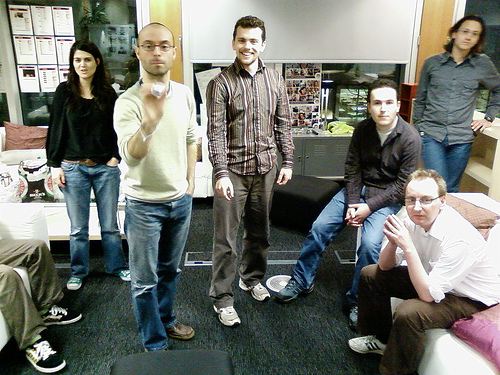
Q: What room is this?
A: It is an office.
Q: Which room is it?
A: It is an office.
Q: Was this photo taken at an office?
A: Yes, it was taken in an office.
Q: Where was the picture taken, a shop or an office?
A: It was taken at an office.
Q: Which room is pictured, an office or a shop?
A: It is an office.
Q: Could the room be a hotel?
A: No, it is an office.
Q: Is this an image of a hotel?
A: No, the picture is showing an office.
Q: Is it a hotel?
A: No, it is an office.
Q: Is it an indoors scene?
A: Yes, it is indoors.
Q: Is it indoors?
A: Yes, it is indoors.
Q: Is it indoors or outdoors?
A: It is indoors.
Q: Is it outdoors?
A: No, it is indoors.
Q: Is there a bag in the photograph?
A: No, there are no bags.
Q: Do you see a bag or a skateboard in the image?
A: No, there are no bags or skateboards.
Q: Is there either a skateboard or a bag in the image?
A: No, there are no bags or skateboards.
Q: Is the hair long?
A: Yes, the hair is long.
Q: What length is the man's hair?
A: The hair is long.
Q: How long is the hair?
A: The hair is long.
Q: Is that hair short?
A: No, the hair is long.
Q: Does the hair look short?
A: No, the hair is long.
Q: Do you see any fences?
A: No, there are no fences.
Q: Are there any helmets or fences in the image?
A: No, there are no fences or helmets.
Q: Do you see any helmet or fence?
A: No, there are no fences or helmets.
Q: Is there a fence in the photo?
A: No, there are no fences.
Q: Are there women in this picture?
A: Yes, there is a woman.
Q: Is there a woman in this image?
A: Yes, there is a woman.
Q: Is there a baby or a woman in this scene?
A: Yes, there is a woman.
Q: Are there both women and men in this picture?
A: Yes, there are both a woman and a man.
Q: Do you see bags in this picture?
A: No, there are no bags.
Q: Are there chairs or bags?
A: No, there are no bags or chairs.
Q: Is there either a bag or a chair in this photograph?
A: No, there are no bags or chairs.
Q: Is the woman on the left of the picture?
A: Yes, the woman is on the left of the image.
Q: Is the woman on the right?
A: No, the woman is on the left of the image.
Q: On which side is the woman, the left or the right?
A: The woman is on the left of the image.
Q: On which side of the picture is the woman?
A: The woman is on the left of the image.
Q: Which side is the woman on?
A: The woman is on the left of the image.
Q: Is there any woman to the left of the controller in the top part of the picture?
A: Yes, there is a woman to the left of the controller.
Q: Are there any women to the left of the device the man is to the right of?
A: Yes, there is a woman to the left of the controller.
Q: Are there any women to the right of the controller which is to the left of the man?
A: No, the woman is to the left of the controller.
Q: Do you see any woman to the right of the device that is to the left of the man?
A: No, the woman is to the left of the controller.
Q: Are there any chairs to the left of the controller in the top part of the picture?
A: No, there is a woman to the left of the controller.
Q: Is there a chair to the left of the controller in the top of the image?
A: No, there is a woman to the left of the controller.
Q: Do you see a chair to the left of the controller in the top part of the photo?
A: No, there is a woman to the left of the controller.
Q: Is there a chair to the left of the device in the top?
A: No, there is a woman to the left of the controller.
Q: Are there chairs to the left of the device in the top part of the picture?
A: No, there is a woman to the left of the controller.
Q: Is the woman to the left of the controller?
A: Yes, the woman is to the left of the controller.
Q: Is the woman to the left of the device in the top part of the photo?
A: Yes, the woman is to the left of the controller.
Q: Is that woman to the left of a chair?
A: No, the woman is to the left of the controller.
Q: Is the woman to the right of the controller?
A: No, the woman is to the left of the controller.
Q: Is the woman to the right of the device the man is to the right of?
A: No, the woman is to the left of the controller.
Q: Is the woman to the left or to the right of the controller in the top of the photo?
A: The woman is to the left of the controller.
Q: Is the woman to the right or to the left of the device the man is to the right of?
A: The woman is to the left of the controller.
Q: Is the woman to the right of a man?
A: No, the woman is to the left of a man.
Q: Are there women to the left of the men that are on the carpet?
A: Yes, there is a woman to the left of the men.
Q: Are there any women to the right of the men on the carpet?
A: No, the woman is to the left of the men.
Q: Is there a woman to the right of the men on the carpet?
A: No, the woman is to the left of the men.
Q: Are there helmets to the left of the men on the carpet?
A: No, there is a woman to the left of the men.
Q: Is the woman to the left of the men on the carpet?
A: Yes, the woman is to the left of the men.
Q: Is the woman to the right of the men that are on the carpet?
A: No, the woman is to the left of the men.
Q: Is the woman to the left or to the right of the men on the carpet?
A: The woman is to the left of the men.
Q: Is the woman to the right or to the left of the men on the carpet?
A: The woman is to the left of the men.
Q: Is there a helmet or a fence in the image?
A: No, there are no helmets or fences.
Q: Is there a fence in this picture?
A: No, there are no fences.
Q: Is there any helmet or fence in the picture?
A: No, there are no fences or helmets.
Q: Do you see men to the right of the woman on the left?
A: Yes, there is a man to the right of the woman.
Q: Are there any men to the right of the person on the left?
A: Yes, there is a man to the right of the woman.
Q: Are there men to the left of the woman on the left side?
A: No, the man is to the right of the woman.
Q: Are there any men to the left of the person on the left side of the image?
A: No, the man is to the right of the woman.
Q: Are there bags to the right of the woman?
A: No, there is a man to the right of the woman.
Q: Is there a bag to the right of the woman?
A: No, there is a man to the right of the woman.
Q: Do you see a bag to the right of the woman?
A: No, there is a man to the right of the woman.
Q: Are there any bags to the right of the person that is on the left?
A: No, there is a man to the right of the woman.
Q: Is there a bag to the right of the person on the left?
A: No, there is a man to the right of the woman.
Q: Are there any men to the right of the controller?
A: Yes, there is a man to the right of the controller.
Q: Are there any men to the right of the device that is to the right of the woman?
A: Yes, there is a man to the right of the controller.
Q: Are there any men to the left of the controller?
A: No, the man is to the right of the controller.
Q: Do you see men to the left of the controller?
A: No, the man is to the right of the controller.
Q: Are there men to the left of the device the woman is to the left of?
A: No, the man is to the right of the controller.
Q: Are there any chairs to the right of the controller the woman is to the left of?
A: No, there is a man to the right of the controller.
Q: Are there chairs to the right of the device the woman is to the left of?
A: No, there is a man to the right of the controller.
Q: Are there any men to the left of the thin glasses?
A: Yes, there is a man to the left of the glasses.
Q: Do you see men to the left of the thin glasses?
A: Yes, there is a man to the left of the glasses.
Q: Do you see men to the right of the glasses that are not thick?
A: No, the man is to the left of the glasses.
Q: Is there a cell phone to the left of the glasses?
A: No, there is a man to the left of the glasses.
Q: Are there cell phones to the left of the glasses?
A: No, there is a man to the left of the glasses.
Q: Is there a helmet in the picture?
A: No, there are no helmets.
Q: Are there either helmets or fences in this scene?
A: No, there are no helmets or fences.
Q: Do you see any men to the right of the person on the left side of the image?
A: Yes, there is a man to the right of the woman.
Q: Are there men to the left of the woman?
A: No, the man is to the right of the woman.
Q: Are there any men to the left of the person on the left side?
A: No, the man is to the right of the woman.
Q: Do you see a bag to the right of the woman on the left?
A: No, there is a man to the right of the woman.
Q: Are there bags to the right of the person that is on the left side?
A: No, there is a man to the right of the woman.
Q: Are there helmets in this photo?
A: No, there are no helmets.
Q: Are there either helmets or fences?
A: No, there are no helmets or fences.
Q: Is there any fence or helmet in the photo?
A: No, there are no helmets or fences.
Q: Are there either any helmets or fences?
A: No, there are no fences or helmets.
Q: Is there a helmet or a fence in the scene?
A: No, there are no fences or helmets.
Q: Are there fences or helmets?
A: No, there are no fences or helmets.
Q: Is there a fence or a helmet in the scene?
A: No, there are no fences or helmets.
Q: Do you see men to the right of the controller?
A: Yes, there is a man to the right of the controller.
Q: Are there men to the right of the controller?
A: Yes, there is a man to the right of the controller.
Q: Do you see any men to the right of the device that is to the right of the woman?
A: Yes, there is a man to the right of the controller.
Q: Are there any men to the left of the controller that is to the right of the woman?
A: No, the man is to the right of the controller.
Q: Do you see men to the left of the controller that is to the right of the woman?
A: No, the man is to the right of the controller.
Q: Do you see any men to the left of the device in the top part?
A: No, the man is to the right of the controller.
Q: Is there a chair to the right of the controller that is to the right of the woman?
A: No, there is a man to the right of the controller.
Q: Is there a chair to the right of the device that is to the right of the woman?
A: No, there is a man to the right of the controller.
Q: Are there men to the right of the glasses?
A: No, the man is to the left of the glasses.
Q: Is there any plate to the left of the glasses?
A: No, there is a man to the left of the glasses.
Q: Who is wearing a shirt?
A: The man is wearing a shirt.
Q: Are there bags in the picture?
A: No, there are no bags.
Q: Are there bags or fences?
A: No, there are no bags or fences.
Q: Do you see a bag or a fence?
A: No, there are no bags or fences.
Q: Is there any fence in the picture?
A: No, there are no fences.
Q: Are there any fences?
A: No, there are no fences.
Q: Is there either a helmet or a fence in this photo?
A: No, there are no fences or helmets.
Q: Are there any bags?
A: No, there are no bags.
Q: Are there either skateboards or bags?
A: No, there are no bags or skateboards.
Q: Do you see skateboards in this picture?
A: No, there are no skateboards.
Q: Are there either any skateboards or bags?
A: No, there are no skateboards or bags.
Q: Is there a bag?
A: No, there are no bags.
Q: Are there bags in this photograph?
A: No, there are no bags.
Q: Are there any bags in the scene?
A: No, there are no bags.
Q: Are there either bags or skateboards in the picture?
A: No, there are no bags or skateboards.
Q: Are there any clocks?
A: No, there are no clocks.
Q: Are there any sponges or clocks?
A: No, there are no clocks or sponges.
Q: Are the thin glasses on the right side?
A: Yes, the glasses are on the right of the image.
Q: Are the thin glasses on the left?
A: No, the glasses are on the right of the image.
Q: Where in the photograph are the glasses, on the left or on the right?
A: The glasses are on the right of the image.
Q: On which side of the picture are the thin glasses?
A: The glasses are on the right of the image.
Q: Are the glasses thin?
A: Yes, the glasses are thin.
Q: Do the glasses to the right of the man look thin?
A: Yes, the glasses are thin.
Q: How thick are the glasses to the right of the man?
A: The glasses are thin.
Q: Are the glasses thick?
A: No, the glasses are thin.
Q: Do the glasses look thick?
A: No, the glasses are thin.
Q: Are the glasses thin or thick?
A: The glasses are thin.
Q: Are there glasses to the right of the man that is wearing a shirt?
A: Yes, there are glasses to the right of the man.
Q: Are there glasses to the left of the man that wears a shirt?
A: No, the glasses are to the right of the man.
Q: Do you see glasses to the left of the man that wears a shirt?
A: No, the glasses are to the right of the man.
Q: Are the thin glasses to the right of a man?
A: Yes, the glasses are to the right of a man.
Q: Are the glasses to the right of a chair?
A: No, the glasses are to the right of a man.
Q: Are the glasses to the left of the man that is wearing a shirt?
A: No, the glasses are to the right of the man.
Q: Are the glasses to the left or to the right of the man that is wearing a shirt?
A: The glasses are to the right of the man.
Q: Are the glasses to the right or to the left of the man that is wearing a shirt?
A: The glasses are to the right of the man.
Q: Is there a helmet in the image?
A: No, there are no helmets.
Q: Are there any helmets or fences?
A: No, there are no helmets or fences.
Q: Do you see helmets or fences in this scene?
A: No, there are no helmets or fences.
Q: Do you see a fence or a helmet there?
A: No, there are no helmets or fences.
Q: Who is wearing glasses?
A: The man is wearing glasses.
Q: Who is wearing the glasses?
A: The man is wearing glasses.